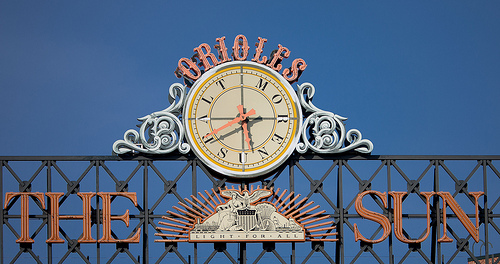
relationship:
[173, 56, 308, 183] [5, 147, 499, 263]
clock on fence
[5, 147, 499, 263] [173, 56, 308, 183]
fence with clock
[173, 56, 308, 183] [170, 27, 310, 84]
clock of orioles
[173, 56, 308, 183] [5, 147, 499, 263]
clock on a fence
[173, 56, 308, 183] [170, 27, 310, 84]
clock on top oriols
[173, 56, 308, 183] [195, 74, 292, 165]
clock with baltimore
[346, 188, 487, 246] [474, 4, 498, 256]
words written on right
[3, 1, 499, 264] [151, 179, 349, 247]
light on logo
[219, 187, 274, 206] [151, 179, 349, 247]
eagle on top of logo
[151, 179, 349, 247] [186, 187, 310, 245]
sun on sign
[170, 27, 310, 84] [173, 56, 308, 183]
writing on top clock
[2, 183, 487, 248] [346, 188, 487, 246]
sign says words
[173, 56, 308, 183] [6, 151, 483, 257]
clock on fence